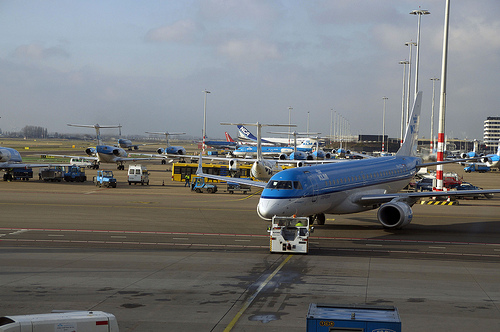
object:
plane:
[197, 142, 499, 230]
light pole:
[431, 0, 452, 192]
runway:
[0, 225, 498, 262]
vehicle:
[267, 214, 310, 254]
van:
[125, 164, 149, 185]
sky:
[0, 0, 499, 107]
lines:
[50, 187, 115, 226]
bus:
[173, 160, 255, 183]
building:
[342, 132, 394, 143]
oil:
[233, 256, 288, 317]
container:
[306, 303, 403, 331]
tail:
[395, 90, 432, 155]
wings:
[360, 188, 499, 201]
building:
[483, 115, 499, 150]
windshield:
[267, 180, 298, 189]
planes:
[202, 123, 318, 159]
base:
[419, 198, 458, 209]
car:
[94, 170, 119, 187]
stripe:
[324, 183, 348, 192]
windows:
[350, 173, 387, 182]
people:
[294, 218, 307, 227]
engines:
[378, 200, 415, 230]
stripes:
[38, 227, 106, 233]